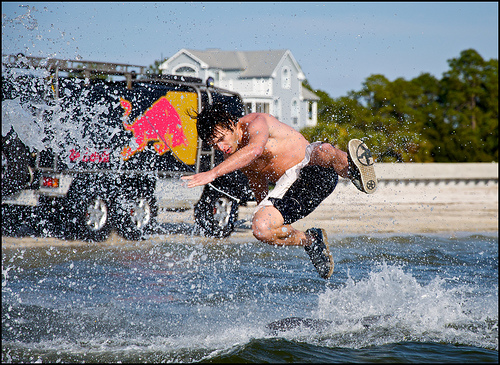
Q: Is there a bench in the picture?
A: No, there are no benches.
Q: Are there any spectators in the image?
A: No, there are no spectators.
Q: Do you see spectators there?
A: No, there are no spectators.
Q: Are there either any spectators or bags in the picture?
A: No, there are no spectators or bags.